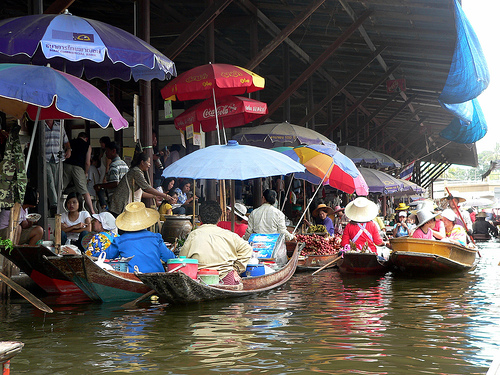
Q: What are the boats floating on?
A: Water.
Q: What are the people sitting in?
A: Boats.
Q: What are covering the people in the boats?
A: Umbrellas.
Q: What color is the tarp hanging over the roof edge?
A: Blue.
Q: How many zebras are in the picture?
A: Zero.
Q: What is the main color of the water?
A: Brown.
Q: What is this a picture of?
A: Boats and umbrellas.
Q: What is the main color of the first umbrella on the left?
A: Blue and purple.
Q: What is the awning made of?
A: Metal.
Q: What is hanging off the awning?
A: Blue plastic.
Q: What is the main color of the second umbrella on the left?
A: Blue.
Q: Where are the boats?
A: In the water.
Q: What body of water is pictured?
A: River.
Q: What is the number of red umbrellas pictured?
A: 2.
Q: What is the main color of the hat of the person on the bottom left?
A: Brown.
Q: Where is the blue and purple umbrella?
A: On the left.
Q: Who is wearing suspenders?
A: The person in red shirt.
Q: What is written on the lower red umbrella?
A: Coca-Cola.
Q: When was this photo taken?
A: Daytime.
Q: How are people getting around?
A: By boat.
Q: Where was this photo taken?
A: Outside on the water.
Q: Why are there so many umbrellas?
A: To protect from the rain.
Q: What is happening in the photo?
A: People are working at a market.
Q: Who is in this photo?
A: People riding boats.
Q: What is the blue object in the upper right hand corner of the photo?
A: Tarp.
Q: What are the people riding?
A: Boats.